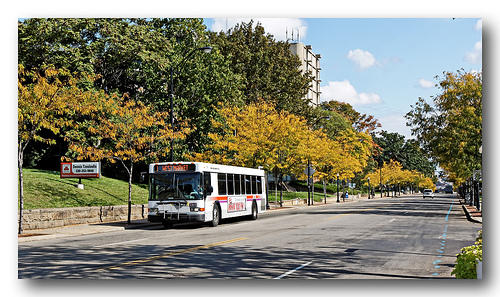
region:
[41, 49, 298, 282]
a white bus on the road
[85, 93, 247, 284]
a white bus on the street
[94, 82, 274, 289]
a bus with windows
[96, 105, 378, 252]
a white bus with windows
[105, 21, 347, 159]
trees with green leaves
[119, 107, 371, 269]
bus parked on the street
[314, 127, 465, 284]
yellow lines on road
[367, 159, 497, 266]
blue lines on road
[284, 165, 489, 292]
white lines on the road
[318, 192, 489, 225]
white lines on the street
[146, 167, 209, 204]
the windshield of the bus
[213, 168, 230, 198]
the window on the bus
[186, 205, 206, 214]
the head light on the bus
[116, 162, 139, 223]
the trunk of the tree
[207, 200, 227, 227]
the wheel of the bus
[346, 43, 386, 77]
a white cloud in the sky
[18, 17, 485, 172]
a cloudy blue sky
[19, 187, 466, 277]
a gray asphalt road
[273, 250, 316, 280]
a white stripe on the road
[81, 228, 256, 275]
a yellow stripe on the road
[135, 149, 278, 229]
A bus.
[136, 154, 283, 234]
The bus is white.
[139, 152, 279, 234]
The bus is on the road.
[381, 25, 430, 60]
The sky is blue.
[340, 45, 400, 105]
A few clouds are in the sky.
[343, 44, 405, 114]
The clouds are white.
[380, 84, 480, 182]
Trees are in the picture.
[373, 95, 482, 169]
The trees have different color leaves.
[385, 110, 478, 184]
The trees have leaves.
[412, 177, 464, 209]
Ohter cars are on the road.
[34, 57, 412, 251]
a bus on the road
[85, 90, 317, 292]
a bus parked on a road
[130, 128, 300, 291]
a bus driving on the road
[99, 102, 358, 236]
a white bus on the road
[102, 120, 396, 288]
a white bus parked on the road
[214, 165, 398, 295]
yellow lines on a road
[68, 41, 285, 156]
green leaves on train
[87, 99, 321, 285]
a white bus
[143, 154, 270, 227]
The bus on the street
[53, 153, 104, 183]
The State Farm sign next to the bus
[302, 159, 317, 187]
The back side of a stop sign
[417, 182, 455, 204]
The backs of cars heading away from the camera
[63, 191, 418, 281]
The yellow line on the road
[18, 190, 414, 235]
The small stone wall near the bus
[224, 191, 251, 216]
The ad on the side of the bus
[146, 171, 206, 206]
The front windshield of the bus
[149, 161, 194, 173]
The digital board on the bus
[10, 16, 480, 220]
The trees that line the street